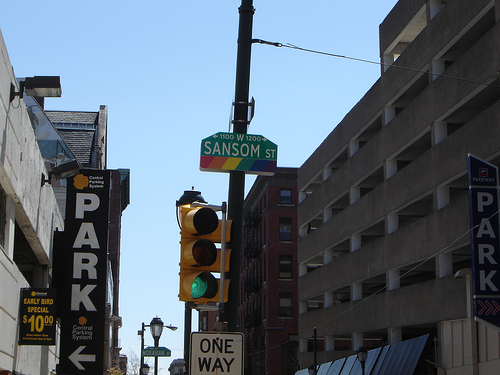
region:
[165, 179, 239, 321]
a stoplight lit to green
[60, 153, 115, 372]
a parking sign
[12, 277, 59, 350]
a parking sign indicating price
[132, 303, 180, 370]
a street lamp with a street sign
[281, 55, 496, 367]
a cement parking garage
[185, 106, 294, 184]
a street sign for Sansom Street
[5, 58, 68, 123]
a flood light on the side of a parking garage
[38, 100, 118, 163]
the roof of a building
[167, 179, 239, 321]
a yellow stoplight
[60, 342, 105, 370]
a white arrow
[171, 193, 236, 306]
The stop light is on green.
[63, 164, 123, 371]
The parking sign is colored black.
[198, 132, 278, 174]
The street sign is colored green.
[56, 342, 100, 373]
This arrow is pointing toward the parking area.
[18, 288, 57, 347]
This sign is advertising a special for ten dollars.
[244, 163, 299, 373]
This building is build with bricks.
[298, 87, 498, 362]
This parking structure is built with concrete.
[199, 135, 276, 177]
The name of this street is Sansom Street.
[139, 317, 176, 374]
This is a street lamp with a street sign.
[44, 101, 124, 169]
This building taller than the other buildings.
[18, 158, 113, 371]
a sign showing parking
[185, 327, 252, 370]
a one way sign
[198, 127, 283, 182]
a green street sign with a rainbow stripe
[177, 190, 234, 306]
a traffic light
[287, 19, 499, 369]
a large parking garage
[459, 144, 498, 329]
a parking sign on the right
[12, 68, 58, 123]
lighting hanging off a building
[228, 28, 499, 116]
a power line hanging across the street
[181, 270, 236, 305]
a green light signal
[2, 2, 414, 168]
a blue sky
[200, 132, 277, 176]
rainbow sign reading 'Sansom St"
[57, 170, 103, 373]
Central Parking System "Park" sign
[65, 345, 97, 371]
white arrow on park sign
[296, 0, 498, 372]
multi-story parking garage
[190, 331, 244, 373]
white one-way traffic sign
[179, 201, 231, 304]
traffic signal with green light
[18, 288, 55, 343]
sign advertising $10.00 parking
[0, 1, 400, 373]
clear blue sky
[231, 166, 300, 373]
red brick multi-story building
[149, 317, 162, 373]
light pole with black base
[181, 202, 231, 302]
a traffic signal with a green light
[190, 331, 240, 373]
top of a one way sign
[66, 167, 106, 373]
parking sign with an arrow pointing left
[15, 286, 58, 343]
a sign with early bird special $10.00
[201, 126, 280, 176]
a street sign with rainbow colors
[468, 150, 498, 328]
a park sign with arrows pointing to the right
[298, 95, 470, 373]
a parking garage with many levels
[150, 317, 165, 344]
an old fashioned looking street light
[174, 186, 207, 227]
partial view of an old fashioned street light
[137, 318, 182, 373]
a street light behind an old fashioned street light